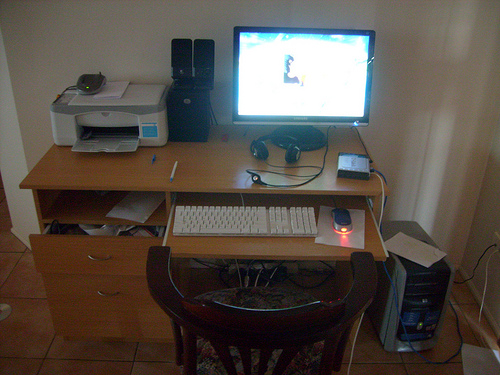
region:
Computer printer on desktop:
[50, 84, 170, 156]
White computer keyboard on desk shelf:
[170, 204, 322, 241]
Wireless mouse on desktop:
[329, 206, 355, 236]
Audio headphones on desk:
[242, 131, 307, 169]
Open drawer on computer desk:
[28, 221, 170, 278]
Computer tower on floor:
[375, 218, 442, 357]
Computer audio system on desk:
[168, 37, 223, 144]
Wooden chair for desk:
[132, 244, 382, 374]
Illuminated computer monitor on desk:
[231, 22, 379, 129]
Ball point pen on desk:
[163, 159, 182, 184]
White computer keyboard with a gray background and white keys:
[175, 202, 322, 242]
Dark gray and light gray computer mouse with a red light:
[323, 205, 360, 240]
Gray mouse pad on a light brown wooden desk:
[322, 200, 367, 252]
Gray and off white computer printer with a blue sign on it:
[48, 74, 179, 150]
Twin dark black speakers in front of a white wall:
[161, 28, 223, 90]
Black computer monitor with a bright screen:
[228, 26, 378, 125]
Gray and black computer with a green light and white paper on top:
[385, 220, 440, 348]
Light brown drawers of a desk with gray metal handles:
[25, 188, 167, 333]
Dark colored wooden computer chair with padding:
[148, 242, 380, 373]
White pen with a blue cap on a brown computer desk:
[165, 148, 179, 190]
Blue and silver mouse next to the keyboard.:
[328, 199, 359, 241]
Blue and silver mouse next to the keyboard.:
[248, 138, 309, 168]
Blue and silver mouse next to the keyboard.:
[338, 139, 369, 183]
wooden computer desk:
[16, 123, 387, 358]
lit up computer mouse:
[330, 203, 357, 240]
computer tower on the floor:
[368, 210, 453, 361]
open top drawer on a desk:
[26, 215, 179, 275]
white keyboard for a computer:
[169, 198, 325, 240]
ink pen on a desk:
[168, 154, 181, 186]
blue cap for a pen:
[148, 151, 158, 166]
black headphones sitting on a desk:
[244, 128, 306, 168]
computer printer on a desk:
[41, 75, 173, 163]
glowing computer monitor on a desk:
[226, 19, 376, 131]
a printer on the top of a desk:
[51, 65, 173, 160]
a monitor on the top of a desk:
[224, 19, 384, 145]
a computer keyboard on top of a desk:
[171, 200, 321, 242]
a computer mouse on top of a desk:
[328, 205, 362, 240]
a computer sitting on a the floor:
[382, 216, 448, 356]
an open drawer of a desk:
[24, 217, 168, 283]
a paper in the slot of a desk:
[101, 196, 169, 227]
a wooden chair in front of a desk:
[153, 252, 384, 367]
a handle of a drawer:
[76, 243, 126, 269]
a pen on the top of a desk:
[164, 154, 184, 183]